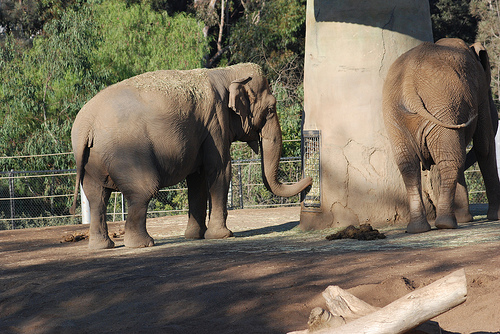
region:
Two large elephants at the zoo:
[25, 7, 499, 254]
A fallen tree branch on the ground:
[266, 257, 481, 327]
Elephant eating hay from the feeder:
[46, 41, 335, 260]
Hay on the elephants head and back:
[91, 52, 275, 105]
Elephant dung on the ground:
[302, 211, 412, 255]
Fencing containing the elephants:
[2, 144, 291, 246]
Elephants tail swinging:
[397, 75, 491, 147]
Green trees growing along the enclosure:
[6, 0, 230, 65]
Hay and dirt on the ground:
[140, 241, 442, 281]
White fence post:
[65, 147, 98, 229]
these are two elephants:
[66, 20, 499, 264]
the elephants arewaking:
[62, 40, 495, 250]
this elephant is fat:
[64, 60, 274, 248]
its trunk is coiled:
[241, 129, 314, 204]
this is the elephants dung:
[323, 220, 380, 244]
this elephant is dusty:
[65, 60, 269, 249]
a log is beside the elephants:
[263, 266, 472, 329]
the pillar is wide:
[314, 5, 381, 225]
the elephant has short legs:
[80, 187, 147, 253]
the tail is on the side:
[415, 98, 485, 142]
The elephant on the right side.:
[375, 33, 497, 238]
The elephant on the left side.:
[67, 55, 310, 260]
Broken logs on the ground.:
[313, 260, 485, 331]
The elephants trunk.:
[261, 126, 310, 203]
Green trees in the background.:
[2, 0, 216, 64]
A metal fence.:
[305, 130, 323, 209]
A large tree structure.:
[305, 0, 430, 233]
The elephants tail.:
[64, 135, 92, 217]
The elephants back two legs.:
[86, 178, 158, 263]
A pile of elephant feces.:
[322, 222, 398, 249]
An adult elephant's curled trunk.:
[256, 119, 316, 203]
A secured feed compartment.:
[298, 132, 333, 208]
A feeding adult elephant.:
[64, 60, 313, 246]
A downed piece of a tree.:
[285, 266, 485, 331]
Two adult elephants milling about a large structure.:
[59, 23, 499, 234]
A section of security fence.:
[4, 164, 71, 226]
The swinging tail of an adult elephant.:
[384, 66, 488, 141]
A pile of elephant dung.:
[323, 216, 390, 248]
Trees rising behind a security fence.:
[5, 5, 297, 60]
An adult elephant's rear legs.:
[386, 136, 474, 234]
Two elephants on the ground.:
[68, 36, 488, 246]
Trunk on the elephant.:
[233, 91, 363, 247]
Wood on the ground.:
[266, 245, 417, 318]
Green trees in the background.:
[25, 20, 205, 91]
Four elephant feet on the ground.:
[71, 171, 242, 262]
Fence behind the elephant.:
[11, 150, 108, 230]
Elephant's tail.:
[398, 75, 488, 141]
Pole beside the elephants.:
[285, 10, 447, 256]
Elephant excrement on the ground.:
[315, 220, 438, 260]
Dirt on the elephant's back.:
[110, 68, 224, 115]